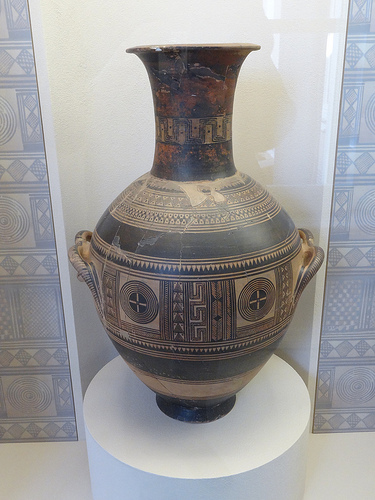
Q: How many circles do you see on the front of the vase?
A: Two.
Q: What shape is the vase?
A: Round.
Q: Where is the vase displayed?
A: On a pedestal.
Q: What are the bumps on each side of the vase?
A: Handles.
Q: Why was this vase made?
A: To hold something.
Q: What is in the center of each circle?
A: A cross.